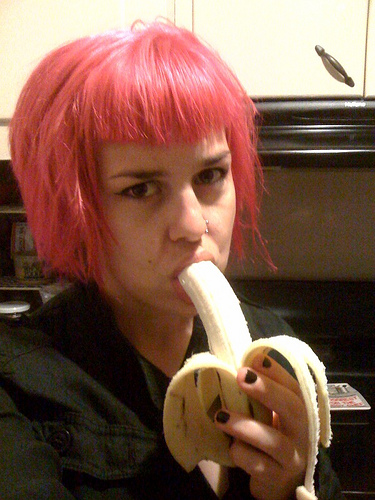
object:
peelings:
[240, 332, 344, 498]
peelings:
[159, 344, 265, 476]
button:
[44, 418, 76, 461]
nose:
[164, 175, 207, 245]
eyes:
[114, 171, 167, 205]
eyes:
[191, 161, 229, 189]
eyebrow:
[105, 160, 164, 181]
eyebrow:
[196, 146, 234, 165]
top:
[1, 265, 346, 497]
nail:
[242, 366, 260, 385]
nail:
[213, 411, 234, 426]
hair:
[9, 16, 290, 308]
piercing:
[205, 215, 214, 228]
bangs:
[86, 83, 227, 152]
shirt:
[0, 280, 343, 500]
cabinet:
[188, 0, 370, 102]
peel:
[158, 332, 360, 500]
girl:
[0, 4, 344, 500]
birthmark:
[133, 247, 176, 287]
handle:
[288, 39, 372, 94]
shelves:
[1, 184, 97, 297]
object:
[292, 378, 372, 431]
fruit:
[166, 257, 333, 492]